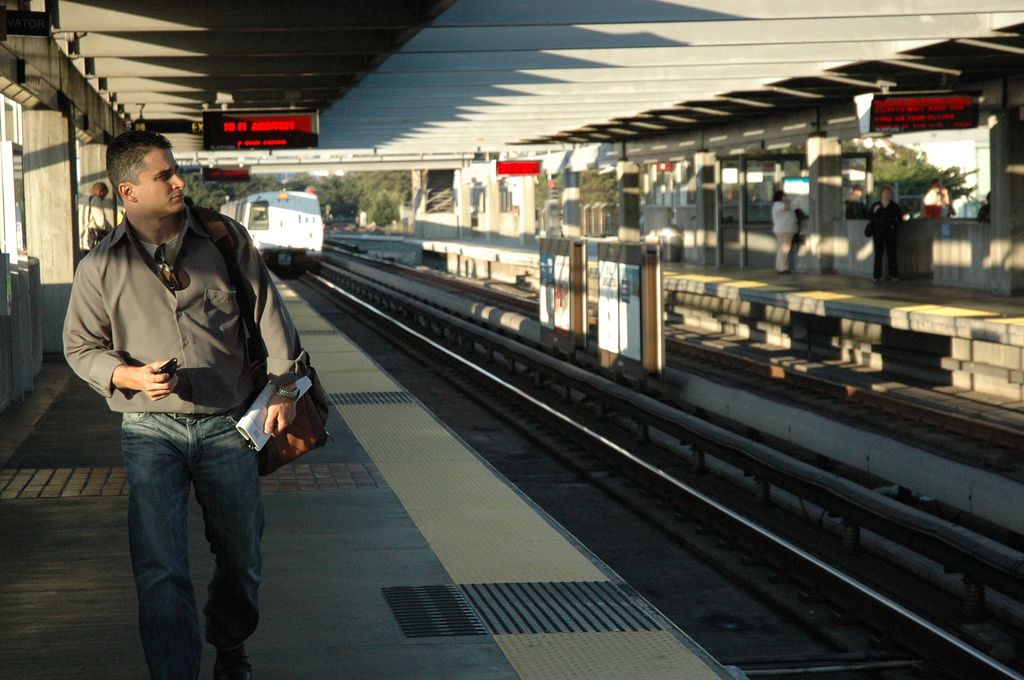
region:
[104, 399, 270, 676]
Blue jeans on a man.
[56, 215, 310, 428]
Gray shirt on a man.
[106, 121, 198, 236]
Dark hair on a man.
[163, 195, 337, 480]
Bag on a man's shoulder.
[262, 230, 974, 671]
Train tracks in a train station.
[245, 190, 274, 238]
Window on a train.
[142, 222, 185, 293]
Sunglasses on a man.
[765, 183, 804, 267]
Person standing on a platform.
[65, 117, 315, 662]
Man walking by train tracks.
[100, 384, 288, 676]
Man wearing pants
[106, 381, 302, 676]
Man is wearing pants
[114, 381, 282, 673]
Man wearing blue pants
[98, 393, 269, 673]
Man is wearing blue pants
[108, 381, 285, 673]
Man wearing jeans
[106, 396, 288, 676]
Man is wearing jeans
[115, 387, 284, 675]
Man wearing blue jeans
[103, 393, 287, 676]
Man is wearing blue jeans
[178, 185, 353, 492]
Man carrying a bag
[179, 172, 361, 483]
Man is carrying a bag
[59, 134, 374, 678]
man walking on the platform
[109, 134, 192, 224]
head is turned to the side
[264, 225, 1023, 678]
train tracks on the ground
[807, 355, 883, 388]
shadow on the tracks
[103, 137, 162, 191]
dark hair on the head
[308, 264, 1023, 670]
metal rod on the train tracks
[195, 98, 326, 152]
red and black sign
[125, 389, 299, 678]
a pair of jeans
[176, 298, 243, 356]
wrinkle on the jacket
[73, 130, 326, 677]
Man standing on train platform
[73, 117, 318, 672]
Man wearing blue jeans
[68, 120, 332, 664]
Man wearing silver watch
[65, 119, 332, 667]
Man holding a cellphone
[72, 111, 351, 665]
Man holding pieces of paper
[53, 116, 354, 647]
Man wearing gray shirt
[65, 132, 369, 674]
Man wearing brown bag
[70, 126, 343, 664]
Man wearing sunglasses in shirt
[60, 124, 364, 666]
Man looking across train tracks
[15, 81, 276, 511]
a man on the sdiewalk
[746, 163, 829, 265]
a person on the sidewalk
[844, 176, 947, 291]
a person on the sidewalk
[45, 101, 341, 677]
man in grey shirt carryign bags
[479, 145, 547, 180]
a red sign that is too far away to read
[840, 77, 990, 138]
a red sign with small blurry letters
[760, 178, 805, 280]
Person in white shirt and tan pants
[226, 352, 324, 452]
white rolled up paper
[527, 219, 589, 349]
a brown billboard that can't be read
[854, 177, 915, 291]
person in black shirt and pants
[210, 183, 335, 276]
Moving white train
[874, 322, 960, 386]
shadow on the wall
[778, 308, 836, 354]
shadow on the wall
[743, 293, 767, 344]
shadow on the wall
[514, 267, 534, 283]
shadow on the wall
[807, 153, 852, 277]
shadow on the wall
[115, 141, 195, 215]
head of a man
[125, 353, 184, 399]
hand of a man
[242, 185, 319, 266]
back of a train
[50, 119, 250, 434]
a person is walking